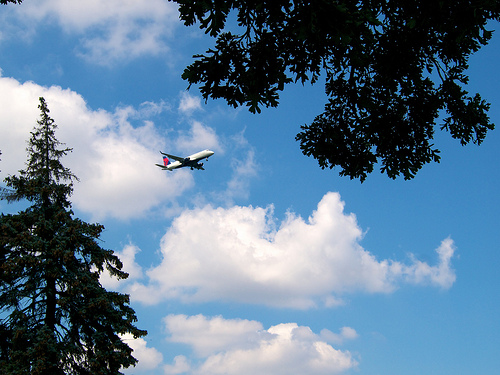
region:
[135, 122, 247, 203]
the plane is white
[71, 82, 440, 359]
the sky is partly cloudy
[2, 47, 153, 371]
the tree is tall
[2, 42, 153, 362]
the tree is an evergreen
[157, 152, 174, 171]
the tail of the plane is red and blue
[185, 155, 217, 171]
the wheels are down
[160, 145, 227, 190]
the bottom of the plane is shadowed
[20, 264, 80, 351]
the branches are thick with leaves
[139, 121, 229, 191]
the plane is high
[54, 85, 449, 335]
the clouds look like smoke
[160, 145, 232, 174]
Delta Airlines airplane in the sky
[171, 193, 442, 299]
white puffy cloud in the blue sky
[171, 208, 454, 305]
white cloud in the sky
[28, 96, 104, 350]
pine tree with green needles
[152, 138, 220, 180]
white plane with red and blue tail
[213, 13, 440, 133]
green leaves on a tree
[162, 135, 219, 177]
plane flying in the sky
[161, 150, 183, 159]
wings on a airplane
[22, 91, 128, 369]
tall pine tree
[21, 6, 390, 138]
blue sky in the daylight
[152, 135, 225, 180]
airplane in the sky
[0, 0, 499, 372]
bright white clouds in the blue sky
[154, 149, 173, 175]
red and blue paint on the tail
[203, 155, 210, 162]
front wheel is down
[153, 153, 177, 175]
tail of the plane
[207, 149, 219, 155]
rounded nose of the plane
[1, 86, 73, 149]
top of a tree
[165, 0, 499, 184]
dark leaves on the tree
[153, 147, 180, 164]
airplane sticking off the side of the plane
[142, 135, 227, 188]
airplane flying by the clouds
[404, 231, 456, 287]
cloud in the sky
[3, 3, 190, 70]
cloud in the sky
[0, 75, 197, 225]
cloud in the sky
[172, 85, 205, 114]
cloud in the sky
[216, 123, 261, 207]
cloud in the sky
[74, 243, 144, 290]
cloud in the sky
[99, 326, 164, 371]
cloud in the sky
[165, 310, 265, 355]
cloud in the sky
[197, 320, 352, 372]
cloud in the sky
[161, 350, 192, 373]
cloud in the sky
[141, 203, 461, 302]
white cloud in the sky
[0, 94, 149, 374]
pine tree growing from ground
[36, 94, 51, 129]
tip of pine tree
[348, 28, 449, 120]
cluster of branches and leaves from tree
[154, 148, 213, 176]
airplane in the sky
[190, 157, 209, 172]
wheels for landing or take off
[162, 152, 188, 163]
side wings for stealing right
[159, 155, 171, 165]
vertical stabilizer wing